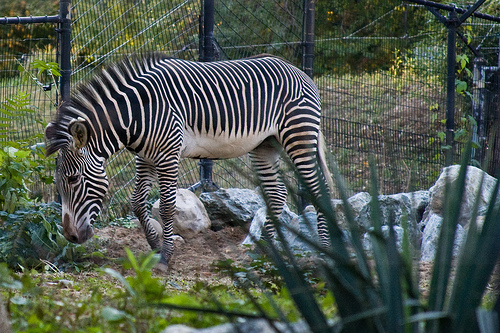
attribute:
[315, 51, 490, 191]
fence — thin, black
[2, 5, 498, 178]
bars — metallic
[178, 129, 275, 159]
belly — white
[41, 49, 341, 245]
zebra — stripped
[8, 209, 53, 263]
plant — small, leafy, green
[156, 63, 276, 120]
stripes — black and white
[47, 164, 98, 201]
eyes — open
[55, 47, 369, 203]
white zebra — black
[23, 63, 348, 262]
stripes — black, white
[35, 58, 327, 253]
zebra — black and white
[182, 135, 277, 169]
underbelly —  plain white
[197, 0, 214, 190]
post — black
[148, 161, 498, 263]
rocks — gray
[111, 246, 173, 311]
plants — green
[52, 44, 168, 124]
mane — short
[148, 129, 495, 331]
plant — large, green, spiky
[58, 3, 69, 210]
fence post — black, metal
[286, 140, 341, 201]
hair — white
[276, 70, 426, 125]
day — bright